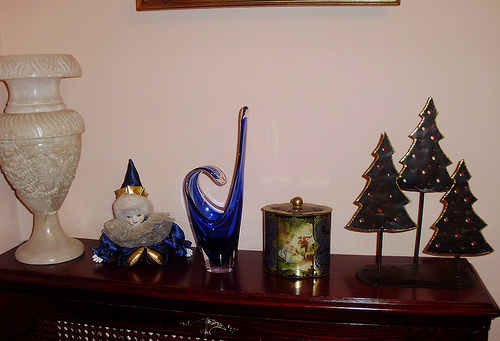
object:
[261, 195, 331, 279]
container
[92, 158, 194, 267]
doll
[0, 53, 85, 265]
vase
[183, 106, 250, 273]
sculpture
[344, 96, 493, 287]
tree decoration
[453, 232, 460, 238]
ornaments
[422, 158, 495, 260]
tree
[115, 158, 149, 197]
hat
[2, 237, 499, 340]
table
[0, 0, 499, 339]
wall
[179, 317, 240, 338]
handle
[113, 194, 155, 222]
hair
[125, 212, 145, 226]
face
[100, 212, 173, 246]
collar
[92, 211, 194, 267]
outfit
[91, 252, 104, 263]
hand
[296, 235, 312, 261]
people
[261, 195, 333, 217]
lid